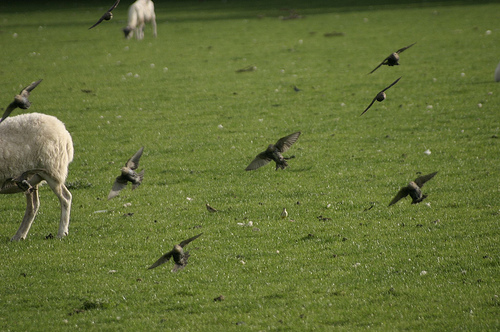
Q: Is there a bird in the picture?
A: Yes, there is a bird.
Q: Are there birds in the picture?
A: Yes, there is a bird.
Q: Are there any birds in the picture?
A: Yes, there is a bird.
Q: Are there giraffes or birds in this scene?
A: Yes, there is a bird.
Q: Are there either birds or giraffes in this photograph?
A: Yes, there is a bird.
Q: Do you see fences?
A: No, there are no fences.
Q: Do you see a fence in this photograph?
A: No, there are no fences.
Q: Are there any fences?
A: No, there are no fences.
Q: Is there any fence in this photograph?
A: No, there are no fences.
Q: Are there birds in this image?
A: Yes, there is a bird.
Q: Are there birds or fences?
A: Yes, there is a bird.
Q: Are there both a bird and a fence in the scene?
A: No, there is a bird but no fences.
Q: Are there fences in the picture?
A: No, there are no fences.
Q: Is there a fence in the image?
A: No, there are no fences.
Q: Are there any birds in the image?
A: Yes, there is a bird.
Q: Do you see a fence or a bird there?
A: Yes, there is a bird.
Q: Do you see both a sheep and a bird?
A: Yes, there are both a bird and a sheep.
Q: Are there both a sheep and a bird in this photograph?
A: Yes, there are both a bird and a sheep.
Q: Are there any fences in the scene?
A: No, there are no fences.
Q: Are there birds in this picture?
A: Yes, there is a bird.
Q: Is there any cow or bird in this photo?
A: Yes, there is a bird.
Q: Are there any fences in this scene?
A: No, there are no fences.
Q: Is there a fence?
A: No, there are no fences.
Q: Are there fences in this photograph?
A: No, there are no fences.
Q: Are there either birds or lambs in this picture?
A: Yes, there is a bird.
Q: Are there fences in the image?
A: No, there are no fences.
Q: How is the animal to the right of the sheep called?
A: The animal is a bird.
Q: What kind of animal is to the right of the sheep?
A: The animal is a bird.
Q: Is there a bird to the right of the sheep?
A: Yes, there is a bird to the right of the sheep.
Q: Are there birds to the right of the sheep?
A: Yes, there is a bird to the right of the sheep.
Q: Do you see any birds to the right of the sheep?
A: Yes, there is a bird to the right of the sheep.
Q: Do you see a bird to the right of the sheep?
A: Yes, there is a bird to the right of the sheep.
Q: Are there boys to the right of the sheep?
A: No, there is a bird to the right of the sheep.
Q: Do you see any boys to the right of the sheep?
A: No, there is a bird to the right of the sheep.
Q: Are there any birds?
A: Yes, there is a bird.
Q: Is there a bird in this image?
A: Yes, there is a bird.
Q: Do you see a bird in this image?
A: Yes, there is a bird.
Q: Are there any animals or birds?
A: Yes, there is a bird.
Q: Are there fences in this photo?
A: No, there are no fences.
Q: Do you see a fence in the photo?
A: No, there are no fences.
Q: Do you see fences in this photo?
A: No, there are no fences.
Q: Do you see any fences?
A: No, there are no fences.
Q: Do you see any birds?
A: Yes, there is a bird.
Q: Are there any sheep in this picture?
A: Yes, there is a sheep.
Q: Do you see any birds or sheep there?
A: Yes, there is a sheep.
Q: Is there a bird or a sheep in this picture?
A: Yes, there is a sheep.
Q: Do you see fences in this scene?
A: No, there are no fences.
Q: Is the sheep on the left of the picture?
A: Yes, the sheep is on the left of the image.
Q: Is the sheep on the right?
A: No, the sheep is on the left of the image.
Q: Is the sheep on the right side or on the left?
A: The sheep is on the left of the image.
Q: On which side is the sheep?
A: The sheep is on the left of the image.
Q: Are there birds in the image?
A: Yes, there is a bird.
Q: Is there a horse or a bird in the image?
A: Yes, there is a bird.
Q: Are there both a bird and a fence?
A: No, there is a bird but no fences.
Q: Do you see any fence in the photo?
A: No, there are no fences.